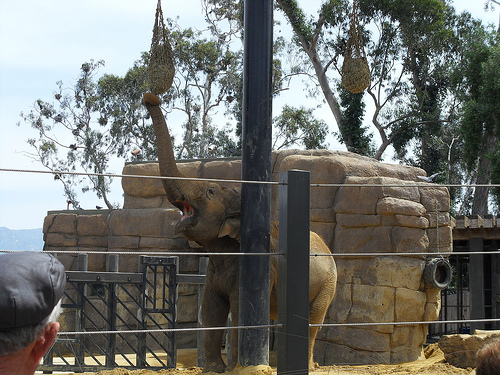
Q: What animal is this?
A: Elephant.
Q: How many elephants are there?
A: 1.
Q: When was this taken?
A: Daytime.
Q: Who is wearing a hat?
A: Man.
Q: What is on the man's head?
A: Hat.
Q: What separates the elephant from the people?
A: Fence.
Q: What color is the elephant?
A: Gray.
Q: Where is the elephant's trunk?
A: In the air.